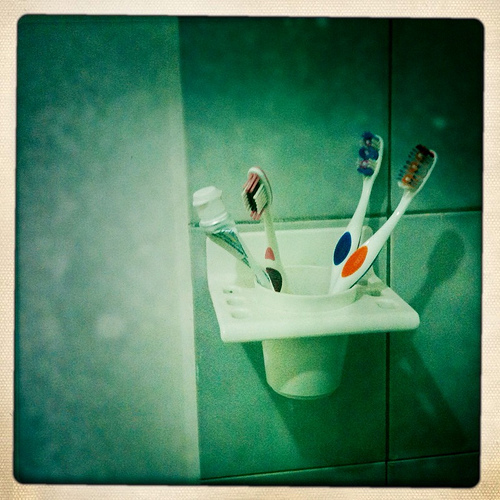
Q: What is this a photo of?
A: Toothbrush holder.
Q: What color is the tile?
A: Green.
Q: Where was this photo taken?
A: In a bathroom.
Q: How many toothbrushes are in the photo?
A: Three.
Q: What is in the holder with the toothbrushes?
A: Toothpaste.